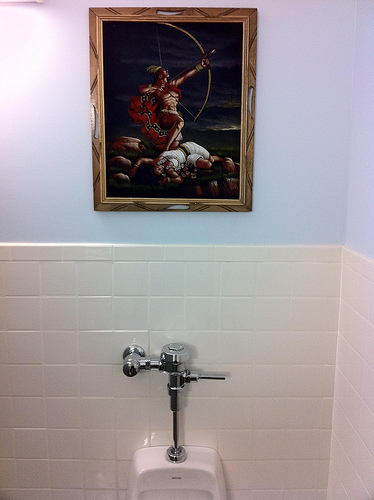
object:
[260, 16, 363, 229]
wall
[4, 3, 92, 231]
blue wall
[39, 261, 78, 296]
tile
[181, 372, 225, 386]
handle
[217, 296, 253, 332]
white tile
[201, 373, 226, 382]
flush handle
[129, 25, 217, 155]
man with bow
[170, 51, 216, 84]
arrow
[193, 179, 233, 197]
fruit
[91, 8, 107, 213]
frame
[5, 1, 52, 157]
cast of light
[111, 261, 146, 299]
tile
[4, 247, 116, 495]
wall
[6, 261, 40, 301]
white wall tile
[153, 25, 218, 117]
bow and arrow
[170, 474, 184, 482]
writing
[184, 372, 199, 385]
flushing handle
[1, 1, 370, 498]
scene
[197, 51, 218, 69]
hand of man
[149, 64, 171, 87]
head of a ma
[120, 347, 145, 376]
pipe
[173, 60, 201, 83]
arm of a ma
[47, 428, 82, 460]
white tiles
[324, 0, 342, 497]
seam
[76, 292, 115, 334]
white tile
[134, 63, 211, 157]
man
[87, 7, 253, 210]
picture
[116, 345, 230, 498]
urinal